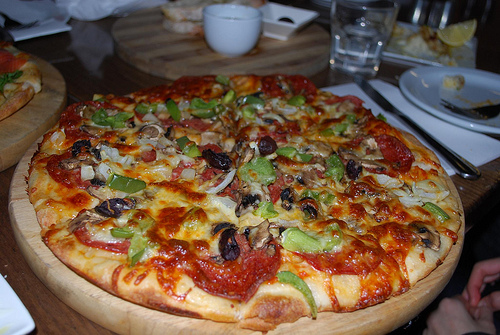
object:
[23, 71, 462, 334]
pizza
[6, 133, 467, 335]
platform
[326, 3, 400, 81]
glass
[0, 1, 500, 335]
table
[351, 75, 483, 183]
knife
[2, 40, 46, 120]
pizza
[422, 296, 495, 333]
hand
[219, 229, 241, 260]
topping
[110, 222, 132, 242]
topping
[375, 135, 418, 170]
topping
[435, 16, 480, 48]
wedge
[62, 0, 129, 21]
cup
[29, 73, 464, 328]
crust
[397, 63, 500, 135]
plate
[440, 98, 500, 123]
fork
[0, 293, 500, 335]
bottom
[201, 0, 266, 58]
bowl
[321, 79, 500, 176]
napkin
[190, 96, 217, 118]
pepper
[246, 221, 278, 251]
mushroom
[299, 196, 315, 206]
olive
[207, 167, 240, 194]
onion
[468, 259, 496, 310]
finger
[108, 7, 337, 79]
plate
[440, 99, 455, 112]
tip